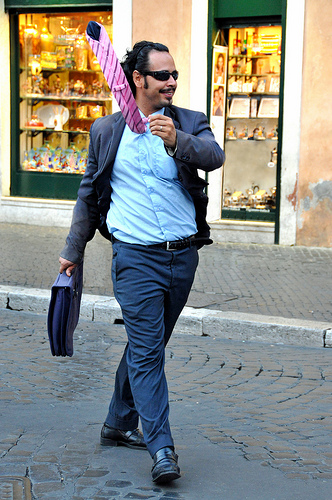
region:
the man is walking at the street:
[79, 50, 211, 494]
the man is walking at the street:
[70, 68, 188, 493]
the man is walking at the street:
[83, 50, 227, 497]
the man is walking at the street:
[80, 50, 234, 497]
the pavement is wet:
[204, 337, 277, 483]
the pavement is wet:
[202, 381, 303, 476]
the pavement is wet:
[196, 398, 303, 495]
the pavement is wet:
[198, 384, 290, 490]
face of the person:
[111, 40, 195, 120]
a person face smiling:
[125, 51, 198, 126]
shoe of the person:
[135, 445, 199, 497]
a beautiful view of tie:
[80, 30, 155, 147]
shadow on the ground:
[157, 481, 179, 498]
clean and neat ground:
[9, 442, 101, 499]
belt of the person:
[142, 222, 198, 249]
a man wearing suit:
[77, 115, 243, 250]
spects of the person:
[142, 57, 199, 88]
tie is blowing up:
[85, 14, 144, 138]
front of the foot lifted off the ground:
[150, 454, 184, 491]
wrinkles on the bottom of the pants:
[135, 401, 176, 451]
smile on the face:
[159, 85, 176, 99]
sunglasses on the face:
[144, 63, 178, 82]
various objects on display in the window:
[16, 11, 113, 183]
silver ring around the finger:
[158, 123, 163, 132]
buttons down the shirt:
[135, 142, 171, 230]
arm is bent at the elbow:
[143, 106, 231, 173]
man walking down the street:
[51, 15, 235, 487]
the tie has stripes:
[101, 56, 116, 77]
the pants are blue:
[140, 349, 153, 377]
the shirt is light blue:
[126, 171, 146, 190]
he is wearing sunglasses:
[151, 68, 185, 83]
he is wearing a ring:
[157, 123, 164, 131]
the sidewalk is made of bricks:
[229, 259, 247, 282]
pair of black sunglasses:
[142, 66, 182, 83]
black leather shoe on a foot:
[150, 432, 182, 488]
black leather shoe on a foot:
[95, 419, 152, 452]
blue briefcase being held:
[38, 251, 88, 363]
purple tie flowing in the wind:
[79, 18, 152, 136]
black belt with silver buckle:
[144, 227, 218, 255]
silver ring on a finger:
[156, 122, 165, 131]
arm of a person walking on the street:
[50, 111, 122, 275]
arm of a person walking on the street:
[145, 104, 229, 173]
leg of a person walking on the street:
[106, 247, 190, 487]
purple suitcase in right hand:
[39, 254, 88, 360]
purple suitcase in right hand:
[38, 255, 92, 358]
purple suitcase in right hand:
[26, 259, 105, 363]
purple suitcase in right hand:
[30, 251, 101, 356]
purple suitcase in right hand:
[30, 255, 103, 362]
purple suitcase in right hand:
[29, 254, 92, 359]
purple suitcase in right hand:
[30, 255, 99, 359]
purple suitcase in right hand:
[35, 259, 96, 359]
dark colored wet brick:
[31, 480, 68, 497]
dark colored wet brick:
[26, 463, 62, 482]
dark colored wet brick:
[74, 483, 98, 497]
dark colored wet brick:
[82, 468, 108, 478]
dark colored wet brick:
[105, 478, 132, 487]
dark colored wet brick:
[199, 429, 221, 437]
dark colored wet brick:
[217, 440, 241, 449]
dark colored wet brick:
[243, 451, 272, 460]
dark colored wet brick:
[296, 459, 320, 465]